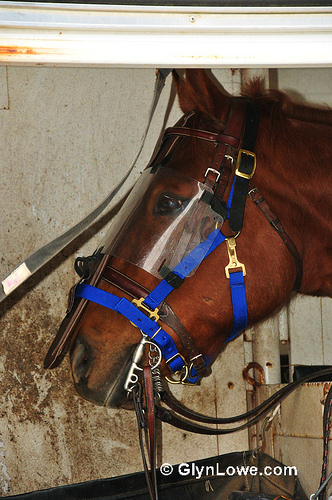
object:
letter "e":
[247, 462, 258, 478]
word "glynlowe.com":
[175, 461, 300, 482]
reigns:
[227, 108, 259, 234]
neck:
[286, 103, 332, 300]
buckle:
[233, 145, 257, 179]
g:
[176, 459, 191, 479]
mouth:
[100, 342, 140, 407]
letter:
[190, 458, 197, 477]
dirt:
[0, 255, 145, 480]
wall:
[0, 67, 251, 496]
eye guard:
[93, 161, 225, 284]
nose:
[69, 327, 100, 388]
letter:
[235, 463, 249, 480]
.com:
[257, 460, 302, 478]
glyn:
[178, 461, 215, 479]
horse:
[64, 68, 332, 410]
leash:
[0, 68, 171, 308]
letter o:
[224, 463, 236, 477]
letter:
[215, 461, 227, 478]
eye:
[150, 191, 189, 217]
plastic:
[93, 162, 228, 283]